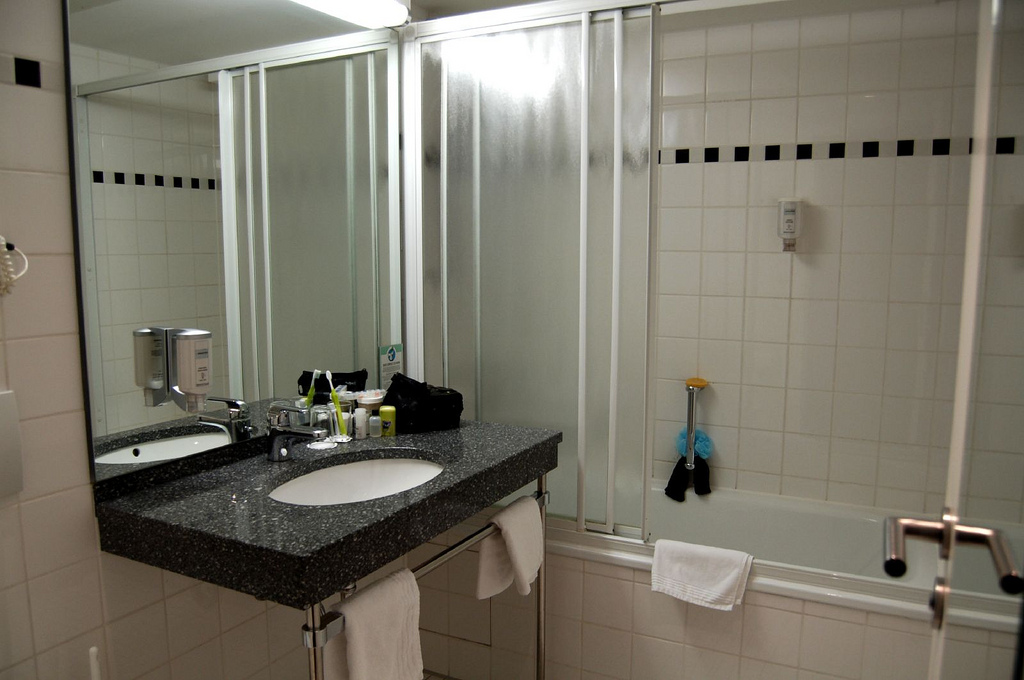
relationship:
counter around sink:
[96, 416, 573, 611] [264, 443, 443, 510]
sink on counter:
[264, 446, 447, 507] [104, 416, 575, 592]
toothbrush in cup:
[305, 361, 345, 403] [326, 398, 349, 438]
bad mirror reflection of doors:
[50, 1, 423, 492] [417, 25, 644, 540]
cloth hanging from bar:
[475, 495, 545, 600] [415, 543, 485, 585]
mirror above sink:
[91, 38, 392, 378] [258, 386, 452, 523]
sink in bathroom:
[264, 443, 443, 510] [14, 12, 1002, 669]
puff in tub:
[673, 427, 716, 465] [294, 419, 1021, 672]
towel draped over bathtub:
[651, 539, 752, 614] [535, 363, 1019, 648]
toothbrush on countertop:
[323, 370, 357, 443] [84, 386, 568, 615]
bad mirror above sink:
[50, 1, 423, 492] [87, 401, 566, 608]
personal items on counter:
[300, 386, 398, 441] [107, 417, 563, 561]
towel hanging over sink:
[651, 460, 829, 673] [264, 446, 447, 507]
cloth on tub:
[471, 494, 544, 603] [404, 472, 1019, 676]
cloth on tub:
[475, 495, 545, 600] [404, 472, 1019, 676]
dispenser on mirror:
[164, 326, 214, 413] [40, 4, 439, 523]